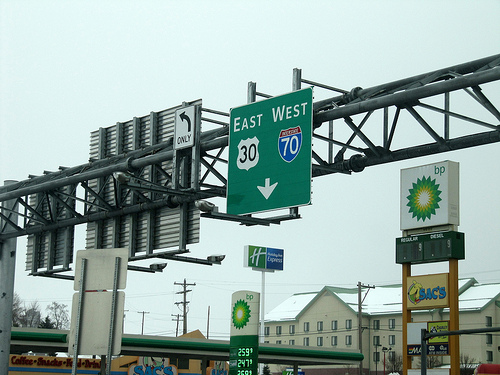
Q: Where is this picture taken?
A: Near highway.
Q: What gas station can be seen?
A: BP.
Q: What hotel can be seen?
A: Hilton.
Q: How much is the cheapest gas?
A: $2.47.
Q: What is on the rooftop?
A: Snow.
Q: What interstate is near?
A: Interstate 70.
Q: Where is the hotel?
A: Next to Sac's.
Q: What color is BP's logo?
A: Green.